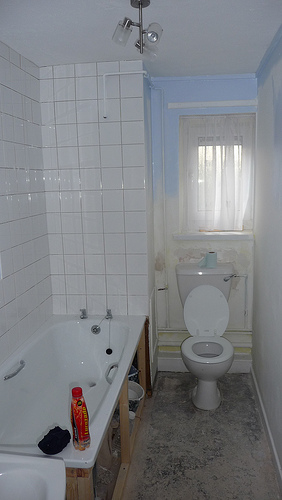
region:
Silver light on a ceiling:
[112, 13, 170, 61]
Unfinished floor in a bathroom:
[162, 435, 261, 486]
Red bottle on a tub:
[63, 382, 101, 463]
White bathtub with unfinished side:
[33, 337, 146, 419]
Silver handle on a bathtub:
[96, 360, 129, 400]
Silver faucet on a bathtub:
[69, 296, 127, 341]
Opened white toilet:
[175, 275, 232, 413]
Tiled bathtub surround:
[50, 163, 177, 280]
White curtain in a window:
[179, 126, 252, 228]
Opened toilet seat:
[179, 279, 233, 375]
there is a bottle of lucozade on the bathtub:
[54, 385, 115, 457]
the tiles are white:
[83, 284, 159, 294]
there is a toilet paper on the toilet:
[197, 251, 232, 272]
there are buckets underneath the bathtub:
[101, 367, 147, 496]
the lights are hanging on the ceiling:
[104, 11, 171, 51]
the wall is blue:
[158, 80, 252, 111]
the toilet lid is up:
[184, 289, 234, 340]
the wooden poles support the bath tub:
[120, 393, 135, 475]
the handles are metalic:
[97, 359, 135, 384]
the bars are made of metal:
[95, 70, 171, 140]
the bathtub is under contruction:
[65, 316, 150, 498]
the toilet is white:
[175, 263, 233, 411]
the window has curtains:
[183, 120, 248, 233]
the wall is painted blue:
[147, 28, 281, 200]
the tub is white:
[1, 314, 149, 466]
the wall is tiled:
[0, 42, 143, 365]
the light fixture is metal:
[110, 0, 159, 60]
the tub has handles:
[1, 360, 117, 385]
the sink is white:
[0, 453, 67, 499]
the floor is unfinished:
[121, 372, 280, 497]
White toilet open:
[164, 244, 248, 426]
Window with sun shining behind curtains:
[174, 110, 260, 239]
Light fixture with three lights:
[101, 1, 169, 59]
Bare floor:
[142, 402, 249, 498]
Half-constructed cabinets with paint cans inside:
[123, 342, 156, 498]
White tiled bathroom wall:
[38, 93, 141, 307]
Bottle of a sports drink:
[61, 379, 97, 455]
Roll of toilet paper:
[191, 249, 221, 273]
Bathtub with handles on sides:
[0, 289, 127, 416]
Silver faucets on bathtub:
[64, 301, 119, 330]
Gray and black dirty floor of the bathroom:
[134, 408, 279, 499]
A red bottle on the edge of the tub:
[68, 386, 92, 451]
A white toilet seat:
[186, 284, 231, 332]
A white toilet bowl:
[179, 336, 250, 409]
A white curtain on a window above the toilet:
[179, 116, 255, 232]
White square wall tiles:
[43, 62, 144, 306]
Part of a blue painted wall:
[154, 74, 256, 98]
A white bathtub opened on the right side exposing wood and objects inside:
[0, 308, 150, 498]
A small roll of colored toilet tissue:
[195, 247, 222, 271]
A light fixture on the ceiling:
[111, 0, 169, 60]